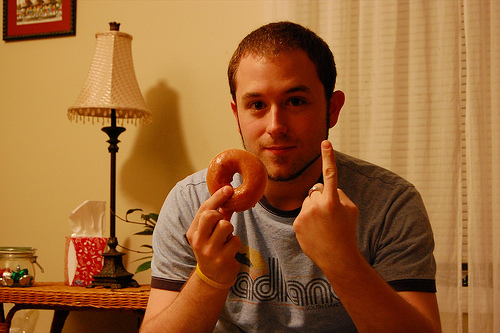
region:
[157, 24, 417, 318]
man holding a donut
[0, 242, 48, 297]
jar of green and silver wrapped candy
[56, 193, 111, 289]
red and white box of tissue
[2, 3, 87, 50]
framed picture on the wall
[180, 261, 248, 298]
yellow bracelet on wrist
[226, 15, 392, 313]
man holding up one index finger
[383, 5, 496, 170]
white curtains over window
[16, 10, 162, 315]
stick lamp on side table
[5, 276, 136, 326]
wicker side table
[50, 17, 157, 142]
white lamp shade with fringe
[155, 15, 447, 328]
the man holds a donut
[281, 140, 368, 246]
a married man holds up one finger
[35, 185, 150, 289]
red tissue box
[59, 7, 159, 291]
tall table lamp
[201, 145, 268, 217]
glazed donut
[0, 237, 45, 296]
candy in a jar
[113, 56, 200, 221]
lamp shade shadow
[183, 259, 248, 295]
live strong bracelet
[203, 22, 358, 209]
a young man with short hair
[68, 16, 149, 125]
tan lamp shade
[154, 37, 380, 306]
a man holding a donut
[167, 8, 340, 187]
a man holding a donut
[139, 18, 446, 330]
mad holding a donut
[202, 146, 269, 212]
brown, glazed, circle donut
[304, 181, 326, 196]
silver ring on middle finger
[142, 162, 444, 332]
blue and brown shirt with logo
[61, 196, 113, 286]
red tissue box with white tissues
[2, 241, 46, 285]
clear and silver jar of candy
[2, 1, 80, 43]
red, white and black picture on the wall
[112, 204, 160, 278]
green plant behind the man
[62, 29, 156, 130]
beige lamp shade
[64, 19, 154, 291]
beige and brown lamp on side tabel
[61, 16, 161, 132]
A fringed lampshade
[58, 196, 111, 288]
A red box of facial tissues with Christmas designs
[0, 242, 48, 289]
A glass jar of Hershey's Kisses in holiday colors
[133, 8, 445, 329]
A man holding a glazed donut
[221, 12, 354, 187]
A man with five o'clock shadow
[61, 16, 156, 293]
A table lamp with a beige lampshade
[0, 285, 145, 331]
Top portion of a wicker table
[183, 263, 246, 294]
A yellow rubber wristband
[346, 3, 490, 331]
Window with a white curtain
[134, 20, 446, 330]
A man holding up index finger